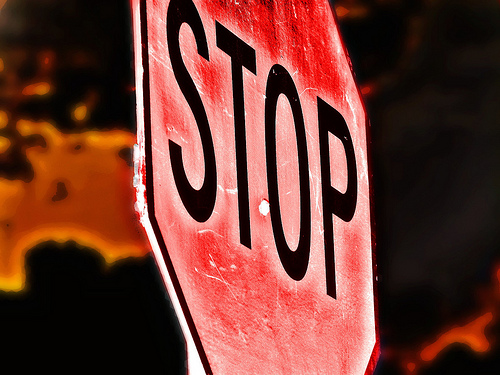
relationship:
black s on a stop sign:
[167, 0, 219, 223] [131, 0, 382, 375]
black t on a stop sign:
[214, 17, 258, 255] [131, 0, 382, 375]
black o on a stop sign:
[263, 62, 313, 281] [131, 0, 382, 375]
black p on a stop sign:
[315, 96, 359, 300] [131, 0, 382, 375]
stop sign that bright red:
[131, 0, 382, 375] [272, 7, 319, 29]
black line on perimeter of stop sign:
[141, 0, 382, 374] [131, 0, 382, 375]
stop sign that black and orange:
[131, 0, 382, 375] [192, 262, 281, 343]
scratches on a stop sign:
[307, 162, 324, 232] [131, 0, 382, 375]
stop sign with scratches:
[131, 0, 382, 375] [307, 162, 324, 232]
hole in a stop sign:
[257, 197, 270, 218] [131, 0, 382, 375]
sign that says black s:
[131, 0, 382, 375] [167, 0, 218, 223]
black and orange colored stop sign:
[192, 262, 281, 343] [131, 0, 382, 375]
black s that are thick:
[167, 0, 218, 223] [215, 20, 258, 76]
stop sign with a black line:
[131, 0, 382, 375] [141, 0, 382, 374]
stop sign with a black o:
[131, 0, 382, 375] [263, 62, 313, 281]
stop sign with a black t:
[131, 0, 382, 375] [214, 17, 258, 255]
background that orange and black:
[1, 1, 499, 374] [38, 188, 125, 279]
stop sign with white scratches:
[131, 0, 382, 375] [307, 162, 324, 232]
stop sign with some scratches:
[131, 0, 382, 375] [307, 162, 324, 232]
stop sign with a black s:
[131, 0, 382, 375] [167, 0, 219, 223]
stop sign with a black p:
[131, 0, 382, 375] [315, 96, 359, 300]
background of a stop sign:
[1, 1, 499, 374] [131, 0, 382, 375]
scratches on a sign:
[307, 162, 324, 232] [131, 0, 382, 375]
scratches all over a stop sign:
[307, 162, 324, 232] [131, 0, 382, 375]